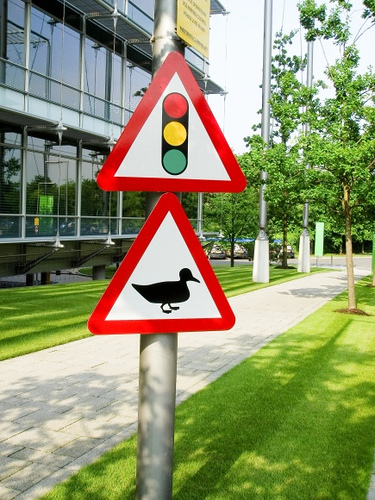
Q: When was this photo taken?
A: During the day.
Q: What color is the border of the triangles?
A: Red.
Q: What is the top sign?
A: Traffic signal.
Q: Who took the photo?
A: A student.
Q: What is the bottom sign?
A: Ducks.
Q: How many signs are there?
A: Just 2.